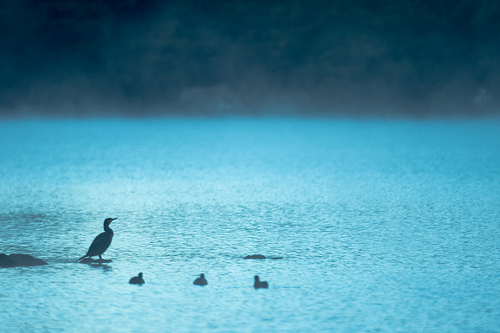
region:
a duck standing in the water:
[83, 213, 117, 264]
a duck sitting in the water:
[129, 272, 145, 282]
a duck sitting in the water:
[193, 268, 212, 285]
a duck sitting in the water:
[249, 272, 269, 289]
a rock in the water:
[242, 250, 283, 263]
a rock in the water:
[2, 248, 49, 271]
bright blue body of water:
[6, 118, 498, 332]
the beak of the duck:
[110, 216, 117, 222]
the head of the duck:
[101, 215, 113, 222]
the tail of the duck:
[72, 249, 88, 260]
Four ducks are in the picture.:
[52, 208, 282, 296]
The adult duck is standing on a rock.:
[68, 204, 126, 268]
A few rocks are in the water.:
[220, 240, 296, 267]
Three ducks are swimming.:
[120, 258, 282, 300]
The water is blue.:
[134, 130, 329, 172]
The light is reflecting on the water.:
[106, 163, 320, 205]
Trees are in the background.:
[11, 3, 468, 74]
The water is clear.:
[161, 137, 343, 212]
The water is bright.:
[161, 152, 376, 229]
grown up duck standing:
[79, 213, 126, 264]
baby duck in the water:
[245, 268, 277, 295]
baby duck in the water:
[184, 270, 214, 287]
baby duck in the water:
[125, 268, 151, 288]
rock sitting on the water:
[9, 243, 52, 281]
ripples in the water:
[229, 199, 341, 245]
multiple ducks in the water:
[14, 126, 461, 326]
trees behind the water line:
[285, 35, 450, 111]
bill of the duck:
[112, 211, 117, 221]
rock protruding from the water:
[249, 247, 284, 267]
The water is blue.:
[199, 160, 363, 223]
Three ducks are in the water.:
[121, 264, 286, 294]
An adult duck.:
[63, 207, 125, 269]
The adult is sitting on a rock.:
[61, 204, 127, 268]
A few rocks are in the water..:
[217, 246, 297, 267]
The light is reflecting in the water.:
[151, 171, 320, 221]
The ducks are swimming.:
[122, 263, 289, 308]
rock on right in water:
[1, 223, 66, 306]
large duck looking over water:
[76, 206, 132, 261]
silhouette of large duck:
[86, 193, 121, 280]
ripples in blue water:
[189, 185, 301, 243]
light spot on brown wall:
[183, 53, 245, 138]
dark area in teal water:
[9, 200, 51, 253]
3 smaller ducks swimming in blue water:
[130, 261, 285, 297]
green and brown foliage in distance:
[285, 31, 390, 118]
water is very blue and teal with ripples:
[268, 117, 426, 195]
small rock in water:
[244, 235, 284, 264]